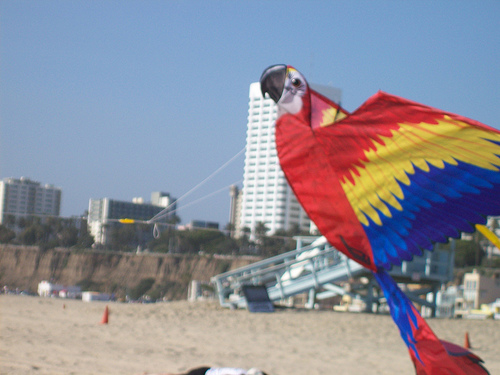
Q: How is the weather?
A: It is cloudy.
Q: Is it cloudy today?
A: Yes, it is cloudy.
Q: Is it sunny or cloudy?
A: It is cloudy.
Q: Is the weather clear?
A: No, it is cloudy.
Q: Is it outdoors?
A: Yes, it is outdoors.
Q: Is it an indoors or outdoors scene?
A: It is outdoors.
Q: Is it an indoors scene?
A: No, it is outdoors.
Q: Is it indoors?
A: No, it is outdoors.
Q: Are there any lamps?
A: No, there are no lamps.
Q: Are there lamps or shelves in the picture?
A: No, there are no lamps or shelves.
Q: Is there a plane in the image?
A: No, there are no airplanes.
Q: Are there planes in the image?
A: No, there are no planes.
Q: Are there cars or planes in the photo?
A: No, there are no planes or cars.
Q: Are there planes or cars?
A: No, there are no planes or cars.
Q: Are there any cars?
A: No, there are no cars.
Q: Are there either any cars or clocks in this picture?
A: No, there are no cars or clocks.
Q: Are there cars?
A: No, there are no cars.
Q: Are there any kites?
A: Yes, there is a kite.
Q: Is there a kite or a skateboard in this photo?
A: Yes, there is a kite.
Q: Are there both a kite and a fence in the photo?
A: Yes, there are both a kite and a fence.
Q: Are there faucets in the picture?
A: No, there are no faucets.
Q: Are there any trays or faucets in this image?
A: No, there are no faucets or trays.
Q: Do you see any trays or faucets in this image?
A: No, there are no faucets or trays.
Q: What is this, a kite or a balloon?
A: This is a kite.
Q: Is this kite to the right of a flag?
A: No, the kite is to the right of a person.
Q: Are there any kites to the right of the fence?
A: Yes, there is a kite to the right of the fence.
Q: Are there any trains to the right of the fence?
A: No, there is a kite to the right of the fence.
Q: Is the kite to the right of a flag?
A: No, the kite is to the right of the fence.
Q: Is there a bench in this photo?
A: No, there are no benches.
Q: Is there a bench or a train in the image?
A: No, there are no benches or trains.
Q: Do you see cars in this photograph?
A: No, there are no cars.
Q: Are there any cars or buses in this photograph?
A: No, there are no cars or buses.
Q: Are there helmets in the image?
A: No, there are no helmets.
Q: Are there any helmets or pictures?
A: No, there are no helmets or pictures.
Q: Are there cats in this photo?
A: No, there are no cats.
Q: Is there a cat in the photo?
A: No, there are no cats.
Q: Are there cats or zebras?
A: No, there are no cats or zebras.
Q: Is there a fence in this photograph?
A: Yes, there is a fence.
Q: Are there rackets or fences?
A: Yes, there is a fence.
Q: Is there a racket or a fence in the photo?
A: Yes, there is a fence.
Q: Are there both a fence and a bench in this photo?
A: No, there is a fence but no benches.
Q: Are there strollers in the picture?
A: No, there are no strollers.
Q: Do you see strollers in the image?
A: No, there are no strollers.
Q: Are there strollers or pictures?
A: No, there are no strollers or pictures.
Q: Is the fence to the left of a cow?
A: No, the fence is to the left of the kite.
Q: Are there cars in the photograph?
A: No, there are no cars.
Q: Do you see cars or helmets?
A: No, there are no cars or helmets.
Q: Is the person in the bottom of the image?
A: Yes, the person is in the bottom of the image.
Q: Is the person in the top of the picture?
A: No, the person is in the bottom of the image.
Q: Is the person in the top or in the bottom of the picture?
A: The person is in the bottom of the image.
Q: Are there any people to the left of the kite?
A: Yes, there is a person to the left of the kite.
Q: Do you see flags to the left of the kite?
A: No, there is a person to the left of the kite.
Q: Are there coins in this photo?
A: No, there are no coins.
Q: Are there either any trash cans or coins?
A: No, there are no coins or trash cans.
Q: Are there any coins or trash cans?
A: No, there are no coins or trash cans.